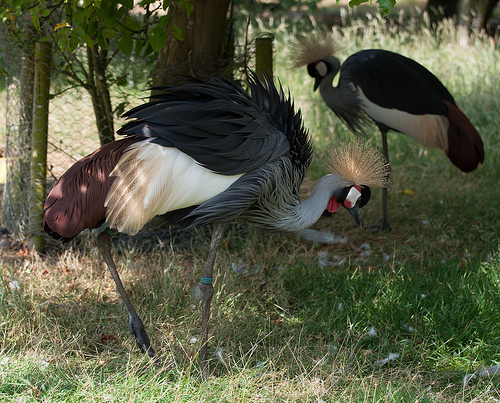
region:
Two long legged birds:
[43, 28, 474, 344]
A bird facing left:
[295, 20, 490, 177]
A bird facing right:
[78, 61, 379, 282]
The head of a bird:
[315, 132, 397, 263]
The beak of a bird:
[342, 203, 372, 236]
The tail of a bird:
[25, 149, 109, 268]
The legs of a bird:
[93, 239, 264, 393]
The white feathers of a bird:
[123, 140, 195, 228]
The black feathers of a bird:
[127, 86, 276, 163]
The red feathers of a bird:
[40, 148, 128, 251]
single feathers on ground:
[355, 318, 423, 378]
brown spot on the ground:
[237, 376, 314, 393]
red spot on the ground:
[7, 236, 40, 275]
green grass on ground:
[188, 264, 460, 363]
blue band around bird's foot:
[178, 264, 233, 285]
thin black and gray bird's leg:
[66, 233, 169, 375]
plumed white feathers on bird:
[105, 141, 235, 242]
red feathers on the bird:
[33, 149, 145, 245]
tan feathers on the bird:
[317, 132, 398, 194]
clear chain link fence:
[58, 94, 98, 137]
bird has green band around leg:
[48, 145, 346, 401]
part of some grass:
[383, 285, 451, 347]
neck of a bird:
[296, 202, 324, 227]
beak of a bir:
[349, 212, 367, 239]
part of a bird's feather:
[107, 189, 150, 224]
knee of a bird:
[190, 275, 225, 310]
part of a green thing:
[196, 273, 215, 291]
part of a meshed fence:
[54, 101, 92, 138]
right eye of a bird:
[356, 191, 363, 203]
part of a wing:
[168, 79, 280, 207]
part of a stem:
[11, 65, 57, 137]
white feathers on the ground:
[348, 319, 410, 375]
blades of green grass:
[163, 342, 217, 386]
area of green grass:
[330, 270, 464, 337]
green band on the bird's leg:
[184, 267, 240, 300]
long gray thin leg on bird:
[73, 229, 135, 319]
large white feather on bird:
[98, 141, 222, 221]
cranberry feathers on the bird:
[11, 138, 141, 249]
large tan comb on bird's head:
[318, 130, 393, 195]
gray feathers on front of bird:
[200, 175, 274, 216]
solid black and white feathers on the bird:
[338, 35, 485, 154]